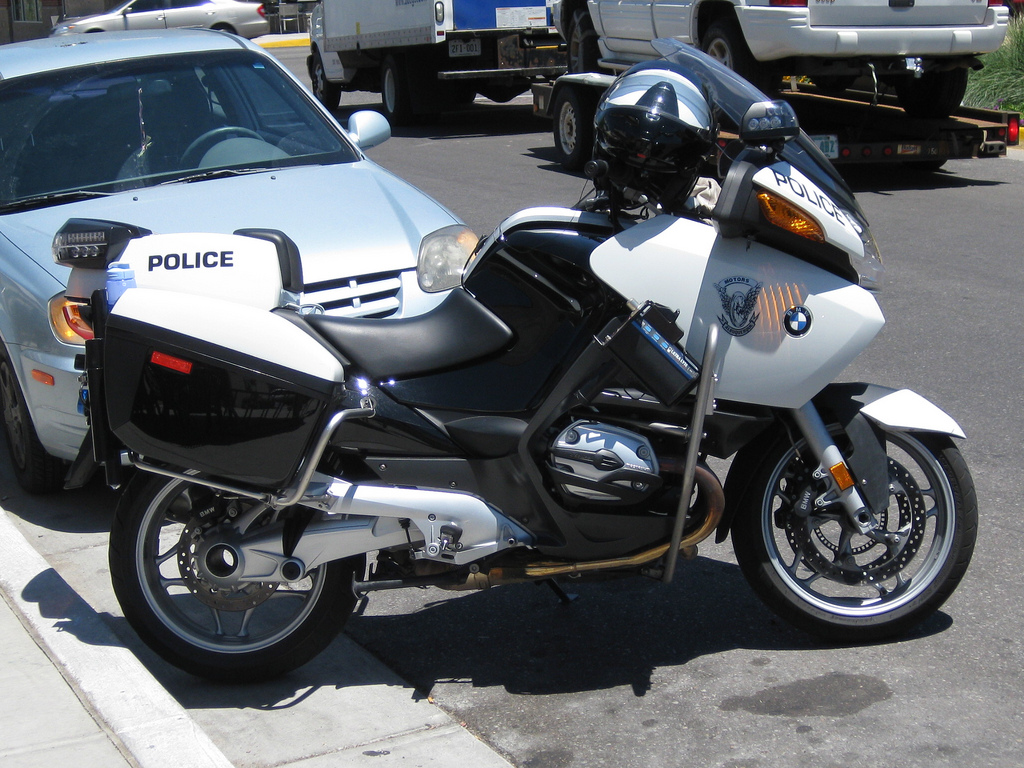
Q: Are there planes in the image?
A: No, there are no planes.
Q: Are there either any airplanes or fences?
A: No, there are no airplanes or fences.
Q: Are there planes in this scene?
A: No, there are no planes.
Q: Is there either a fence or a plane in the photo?
A: No, there are no airplanes or fences.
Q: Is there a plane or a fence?
A: No, there are no airplanes or fences.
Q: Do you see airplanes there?
A: No, there are no airplanes.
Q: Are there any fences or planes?
A: No, there are no planes or fences.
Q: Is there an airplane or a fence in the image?
A: No, there are no airplanes or fences.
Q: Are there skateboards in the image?
A: No, there are no skateboards.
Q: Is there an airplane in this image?
A: No, there are no airplanes.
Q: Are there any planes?
A: No, there are no planes.